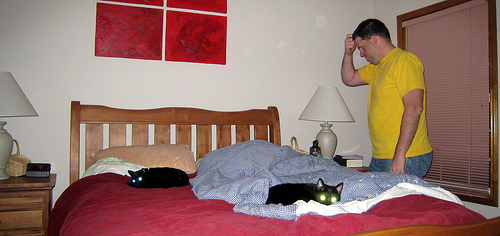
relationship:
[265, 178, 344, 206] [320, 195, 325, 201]
cat has an eye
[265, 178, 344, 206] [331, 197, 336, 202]
cat has an eye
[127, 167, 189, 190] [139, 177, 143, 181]
cat has an eye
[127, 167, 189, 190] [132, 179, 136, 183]
cat has an eye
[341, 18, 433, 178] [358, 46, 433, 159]
man wearing a shirt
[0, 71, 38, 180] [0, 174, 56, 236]
lamp on table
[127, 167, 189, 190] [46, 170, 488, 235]
cat laying on a blanket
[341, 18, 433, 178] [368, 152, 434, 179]
man wearing jeans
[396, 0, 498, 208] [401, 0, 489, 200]
window has blinds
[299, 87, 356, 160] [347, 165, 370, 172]
lamp on table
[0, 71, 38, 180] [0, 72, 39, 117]
lamp has a shade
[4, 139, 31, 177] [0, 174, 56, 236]
basket on table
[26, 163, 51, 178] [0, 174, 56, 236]
alarm clock on table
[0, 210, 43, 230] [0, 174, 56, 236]
drawer in table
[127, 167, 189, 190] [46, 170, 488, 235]
cat on blanket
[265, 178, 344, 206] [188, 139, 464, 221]
cat on a blanket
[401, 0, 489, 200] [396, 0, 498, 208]
blinds are on window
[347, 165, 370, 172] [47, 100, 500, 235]
table beside bed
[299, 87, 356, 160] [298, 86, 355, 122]
lamp has a shade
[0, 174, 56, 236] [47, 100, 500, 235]
table beside bed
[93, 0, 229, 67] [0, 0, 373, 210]
artwork on wall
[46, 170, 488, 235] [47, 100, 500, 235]
blanket on bed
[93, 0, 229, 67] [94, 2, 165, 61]
artwork has a section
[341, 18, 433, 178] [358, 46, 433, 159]
man has a shirt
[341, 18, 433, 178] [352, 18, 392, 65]
man has a head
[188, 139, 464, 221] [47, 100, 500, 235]
blanket on bed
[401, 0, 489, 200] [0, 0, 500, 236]
blinds are in house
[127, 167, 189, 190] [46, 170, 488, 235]
cat sleeping on a blanket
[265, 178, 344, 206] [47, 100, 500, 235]
cat sleeping on a bed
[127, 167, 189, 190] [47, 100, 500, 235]
cat sleeping on a bed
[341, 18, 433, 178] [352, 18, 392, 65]
man scratching h head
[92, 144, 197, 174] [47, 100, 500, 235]
pillow on bed